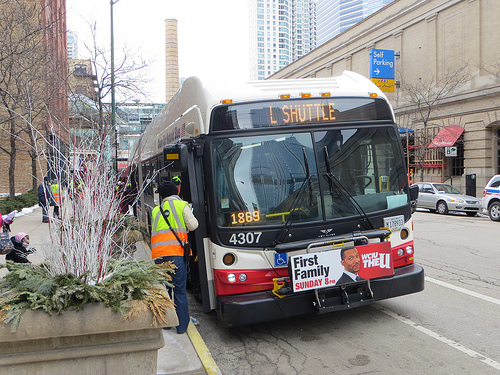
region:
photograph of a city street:
[13, 4, 480, 364]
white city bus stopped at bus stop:
[123, 67, 417, 334]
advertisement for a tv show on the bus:
[286, 236, 398, 294]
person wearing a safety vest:
[145, 175, 200, 336]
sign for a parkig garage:
[368, 46, 406, 97]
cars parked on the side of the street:
[404, 165, 498, 219]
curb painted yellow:
[183, 318, 229, 370]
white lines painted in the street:
[436, 265, 482, 360]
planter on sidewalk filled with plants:
[8, 108, 165, 369]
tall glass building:
[253, 0, 389, 76]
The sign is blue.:
[367, 45, 401, 80]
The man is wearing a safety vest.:
[143, 198, 200, 263]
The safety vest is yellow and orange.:
[145, 195, 185, 257]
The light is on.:
[264, 100, 344, 126]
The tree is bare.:
[6, 93, 143, 278]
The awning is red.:
[420, 125, 465, 152]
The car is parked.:
[415, 173, 499, 216]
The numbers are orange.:
[225, 206, 263, 228]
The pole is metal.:
[107, 0, 120, 177]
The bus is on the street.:
[121, 75, 426, 325]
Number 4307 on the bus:
[224, 229, 265, 249]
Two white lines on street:
[371, 273, 498, 372]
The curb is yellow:
[181, 316, 222, 373]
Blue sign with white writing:
[367, 45, 397, 81]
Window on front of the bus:
[208, 126, 410, 227]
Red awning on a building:
[422, 123, 466, 151]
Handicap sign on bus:
[270, 248, 290, 270]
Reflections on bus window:
[213, 134, 368, 217]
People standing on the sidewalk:
[30, 170, 87, 228]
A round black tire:
[430, 197, 452, 218]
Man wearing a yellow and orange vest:
[145, 178, 192, 264]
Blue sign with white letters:
[369, 43, 396, 80]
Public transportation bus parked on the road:
[115, 66, 432, 330]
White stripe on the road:
[407, 319, 466, 354]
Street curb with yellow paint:
[190, 334, 225, 374]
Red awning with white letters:
[427, 121, 467, 150]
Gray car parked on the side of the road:
[411, 180, 483, 215]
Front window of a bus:
[195, 122, 413, 233]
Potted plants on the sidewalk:
[2, 80, 184, 374]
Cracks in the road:
[215, 335, 334, 374]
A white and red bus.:
[111, 70, 431, 325]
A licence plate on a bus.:
[383, 217, 405, 230]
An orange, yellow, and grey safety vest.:
[149, 200, 191, 257]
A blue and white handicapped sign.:
[271, 252, 287, 265]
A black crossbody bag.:
[157, 202, 197, 261]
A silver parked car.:
[403, 174, 483, 221]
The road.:
[137, 159, 497, 374]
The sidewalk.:
[0, 174, 198, 374]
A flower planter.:
[0, 275, 182, 373]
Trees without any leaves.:
[0, 3, 498, 280]